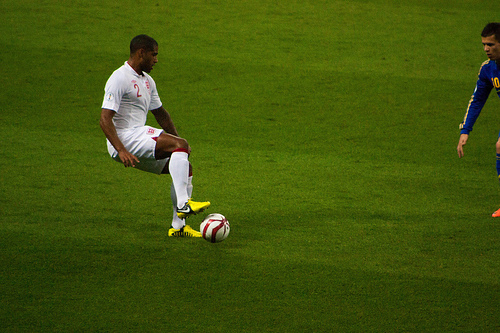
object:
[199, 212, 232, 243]
soccer ball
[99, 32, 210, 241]
man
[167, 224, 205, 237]
shoes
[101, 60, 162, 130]
jersey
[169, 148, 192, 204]
sock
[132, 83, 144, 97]
number 2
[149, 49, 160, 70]
face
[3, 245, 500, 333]
grass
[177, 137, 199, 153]
knee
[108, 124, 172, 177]
shorts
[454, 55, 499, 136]
shirt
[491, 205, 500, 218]
cleat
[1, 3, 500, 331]
field